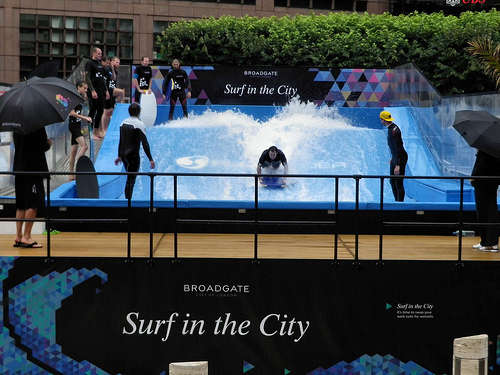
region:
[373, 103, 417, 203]
This is a person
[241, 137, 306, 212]
This is a person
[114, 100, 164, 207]
This is a person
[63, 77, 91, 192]
This is a person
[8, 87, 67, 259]
This is a person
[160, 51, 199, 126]
This is a person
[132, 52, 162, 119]
This is a person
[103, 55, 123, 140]
This is a person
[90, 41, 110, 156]
This is a person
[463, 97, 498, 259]
This is a person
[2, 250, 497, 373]
sign on black wall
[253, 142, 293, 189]
man on surfboard in water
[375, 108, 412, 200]
man wearing yellow cap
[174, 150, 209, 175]
symbol under the water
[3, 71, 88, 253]
man holding umbrella watching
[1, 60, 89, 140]
umbrella is black with a print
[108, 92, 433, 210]
water running down a ramp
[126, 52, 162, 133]
man holding a surfboard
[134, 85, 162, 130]
man's surfboard is white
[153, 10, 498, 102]
row of bushes behind water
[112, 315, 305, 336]
white writing on black background.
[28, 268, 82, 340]
wave design on black background.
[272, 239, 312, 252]
wooden flooring on platform.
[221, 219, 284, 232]
black fencing on platform.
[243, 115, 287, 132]
waves in the water.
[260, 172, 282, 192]
blue surfboard in the water.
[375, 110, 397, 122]
yellow cap on man.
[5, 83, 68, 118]
black umbrella over person's head.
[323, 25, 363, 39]
leaves on the bushes.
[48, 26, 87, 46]
window on the building.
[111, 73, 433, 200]
a water slide for surfing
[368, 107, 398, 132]
a man wearing a yellow hat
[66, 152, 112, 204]
a black surf board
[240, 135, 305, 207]
a man on a surf board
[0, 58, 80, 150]
a woman holding a umbrella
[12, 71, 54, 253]
a woman wearing a dress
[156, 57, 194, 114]
a man holding a surf board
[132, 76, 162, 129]
a white surf board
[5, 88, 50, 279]
a woman wearing sandles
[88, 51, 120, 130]
three men wearing wetsuits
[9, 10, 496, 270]
this is a public surf pool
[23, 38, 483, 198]
these people are enjoying the pool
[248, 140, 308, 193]
this man is surfing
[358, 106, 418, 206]
this is a spectator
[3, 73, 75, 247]
this person has an umbrella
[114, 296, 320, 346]
this is the advertisement for this pool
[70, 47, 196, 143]
these people are waiting to get in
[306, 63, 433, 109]
colorful decoration on the sign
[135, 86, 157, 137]
a white surfboard by the man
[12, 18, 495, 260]
this surf pool is in the city